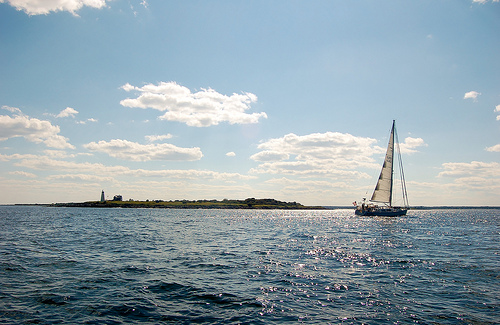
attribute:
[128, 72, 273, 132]
clouds — white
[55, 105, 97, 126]
clouds — white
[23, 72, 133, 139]
sky — blue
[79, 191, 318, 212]
land — green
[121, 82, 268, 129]
clouds — white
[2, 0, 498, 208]
sky — clear, blue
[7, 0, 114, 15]
clouds — white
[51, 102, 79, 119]
clouds — white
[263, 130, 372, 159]
clouds — white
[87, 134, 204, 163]
clouds — white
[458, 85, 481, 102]
clouds — white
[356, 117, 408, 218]
boat — small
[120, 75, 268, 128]
cloud — white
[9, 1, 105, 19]
cloud — white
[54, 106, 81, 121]
cloud — white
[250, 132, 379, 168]
cloud — white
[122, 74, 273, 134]
clouds — white, puffy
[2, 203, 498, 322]
water — blue, deep, calm, large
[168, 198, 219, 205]
grass — green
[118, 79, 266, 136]
cloud — white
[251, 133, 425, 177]
cloud — white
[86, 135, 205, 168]
cloud — white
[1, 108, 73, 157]
cloud — white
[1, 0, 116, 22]
cloud — white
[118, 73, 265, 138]
clouds — white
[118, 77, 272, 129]
clouds — white, fluffy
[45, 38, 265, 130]
clouds sky — white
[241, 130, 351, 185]
clouds sky — white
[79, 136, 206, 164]
cloud — white, fluffy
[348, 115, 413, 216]
boat — white, small, blue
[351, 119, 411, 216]
boat — blue, white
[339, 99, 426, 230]
boat — blue, small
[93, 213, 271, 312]
water — calm, blue